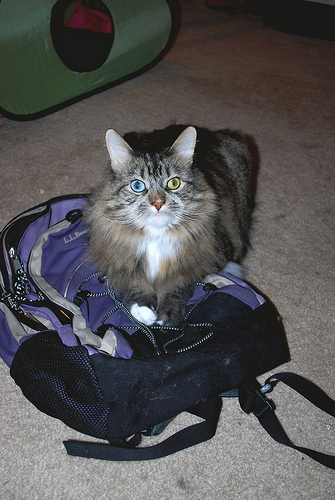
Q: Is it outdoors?
A: Yes, it is outdoors.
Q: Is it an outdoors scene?
A: Yes, it is outdoors.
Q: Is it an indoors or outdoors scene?
A: It is outdoors.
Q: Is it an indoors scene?
A: No, it is outdoors.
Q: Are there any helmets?
A: No, there are no helmets.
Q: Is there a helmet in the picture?
A: No, there are no helmets.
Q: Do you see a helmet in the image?
A: No, there are no helmets.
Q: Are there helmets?
A: No, there are no helmets.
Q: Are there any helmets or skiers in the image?
A: No, there are no helmets or skiers.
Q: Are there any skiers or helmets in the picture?
A: No, there are no helmets or skiers.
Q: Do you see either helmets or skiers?
A: No, there are no helmets or skiers.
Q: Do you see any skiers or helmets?
A: No, there are no helmets or skiers.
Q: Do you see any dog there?
A: No, there are no dogs.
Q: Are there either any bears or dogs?
A: No, there are no dogs or bears.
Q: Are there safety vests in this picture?
A: No, there are no safety vests.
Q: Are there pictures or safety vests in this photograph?
A: No, there are no safety vests or pictures.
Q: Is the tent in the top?
A: Yes, the tent is in the top of the image.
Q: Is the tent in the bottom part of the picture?
A: No, the tent is in the top of the image.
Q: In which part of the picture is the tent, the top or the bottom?
A: The tent is in the top of the image.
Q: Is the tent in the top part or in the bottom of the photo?
A: The tent is in the top of the image.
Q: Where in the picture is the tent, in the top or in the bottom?
A: The tent is in the top of the image.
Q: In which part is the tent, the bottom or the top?
A: The tent is in the top of the image.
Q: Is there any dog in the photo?
A: No, there are no dogs.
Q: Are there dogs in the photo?
A: No, there are no dogs.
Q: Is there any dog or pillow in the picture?
A: No, there are no dogs or pillows.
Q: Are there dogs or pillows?
A: No, there are no dogs or pillows.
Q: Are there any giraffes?
A: No, there are no giraffes.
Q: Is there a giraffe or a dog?
A: No, there are no giraffes or dogs.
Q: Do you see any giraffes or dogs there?
A: No, there are no giraffes or dogs.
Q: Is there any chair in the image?
A: No, there are no chairs.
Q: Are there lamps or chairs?
A: No, there are no chairs or lamps.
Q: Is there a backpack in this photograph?
A: Yes, there is a backpack.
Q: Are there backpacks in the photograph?
A: Yes, there is a backpack.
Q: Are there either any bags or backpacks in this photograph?
A: Yes, there is a backpack.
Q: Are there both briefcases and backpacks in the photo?
A: No, there is a backpack but no briefcases.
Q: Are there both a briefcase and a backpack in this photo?
A: No, there is a backpack but no briefcases.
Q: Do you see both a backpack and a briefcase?
A: No, there is a backpack but no briefcases.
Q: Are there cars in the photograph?
A: No, there are no cars.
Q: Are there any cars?
A: No, there are no cars.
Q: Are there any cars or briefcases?
A: No, there are no cars or briefcases.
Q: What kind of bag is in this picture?
A: The bag is a backpack.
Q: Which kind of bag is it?
A: The bag is a backpack.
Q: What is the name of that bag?
A: This is a backpack.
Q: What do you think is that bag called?
A: This is a backpack.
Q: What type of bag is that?
A: This is a backpack.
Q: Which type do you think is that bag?
A: This is a backpack.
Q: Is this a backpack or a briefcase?
A: This is a backpack.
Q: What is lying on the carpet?
A: The backpack is lying on the carpet.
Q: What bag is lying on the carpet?
A: The bag is a backpack.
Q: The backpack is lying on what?
A: The backpack is lying on the carpet.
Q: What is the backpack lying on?
A: The backpack is lying on the carpet.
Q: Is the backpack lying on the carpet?
A: Yes, the backpack is lying on the carpet.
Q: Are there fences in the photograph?
A: No, there are no fences.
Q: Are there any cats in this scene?
A: Yes, there is a cat.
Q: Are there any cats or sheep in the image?
A: Yes, there is a cat.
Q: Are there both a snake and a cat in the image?
A: No, there is a cat but no snakes.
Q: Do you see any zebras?
A: No, there are no zebras.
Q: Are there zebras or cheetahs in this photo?
A: No, there are no zebras or cheetahs.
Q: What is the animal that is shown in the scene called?
A: The animal is a cat.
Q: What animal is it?
A: The animal is a cat.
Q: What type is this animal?
A: That is a cat.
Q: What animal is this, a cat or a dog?
A: That is a cat.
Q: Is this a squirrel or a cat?
A: This is a cat.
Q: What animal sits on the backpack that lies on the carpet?
A: The cat sits on the backpack.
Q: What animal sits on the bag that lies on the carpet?
A: The cat sits on the backpack.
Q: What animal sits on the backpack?
A: The cat sits on the backpack.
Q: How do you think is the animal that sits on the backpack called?
A: The animal is a cat.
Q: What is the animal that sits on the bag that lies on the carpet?
A: The animal is a cat.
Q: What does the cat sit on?
A: The cat sits on the backpack.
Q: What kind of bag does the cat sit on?
A: The cat sits on the backpack.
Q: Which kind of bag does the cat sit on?
A: The cat sits on the backpack.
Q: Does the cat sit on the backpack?
A: Yes, the cat sits on the backpack.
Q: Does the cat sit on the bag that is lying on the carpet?
A: Yes, the cat sits on the backpack.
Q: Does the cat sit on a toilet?
A: No, the cat sits on the backpack.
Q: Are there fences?
A: No, there are no fences.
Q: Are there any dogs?
A: No, there are no dogs.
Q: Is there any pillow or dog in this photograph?
A: No, there are no dogs or pillows.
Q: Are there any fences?
A: No, there are no fences.